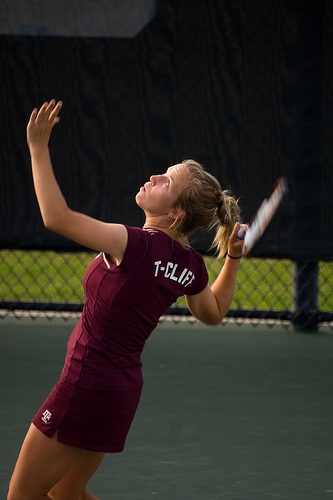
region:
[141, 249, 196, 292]
White letters on shirt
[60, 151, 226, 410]
Women wearing a red shirt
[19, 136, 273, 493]
The women is playing tennis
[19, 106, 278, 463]
The women is holding a tennis racket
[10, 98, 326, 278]
The tarp on the fence is black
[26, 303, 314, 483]
The court is green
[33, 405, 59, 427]
White logo on shorts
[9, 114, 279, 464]
The women is swinging the tennis racket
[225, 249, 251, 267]
The bracelet is black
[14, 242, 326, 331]
The chain link fence is black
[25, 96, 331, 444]
the player is looking up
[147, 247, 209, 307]
the text says T-Cliff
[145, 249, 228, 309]
the text is white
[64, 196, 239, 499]
the uniform is maroon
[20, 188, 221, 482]
the player is wearing a uniform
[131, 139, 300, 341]
the player is holding a racket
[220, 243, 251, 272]
the player is wearing a bracelet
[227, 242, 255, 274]
the bracelet is black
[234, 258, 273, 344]
grass outside the fence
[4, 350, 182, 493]
the skirt is maroon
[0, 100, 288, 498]
a female tennis player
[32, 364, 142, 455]
a dark red skirt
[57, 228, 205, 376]
a dark red sleeveless jersey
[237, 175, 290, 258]
a blurred tennis racket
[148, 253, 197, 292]
printed name T-CLIFF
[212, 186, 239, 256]
a woman's pony tail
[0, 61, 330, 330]
a black chain link fence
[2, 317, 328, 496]
a dark green tennis court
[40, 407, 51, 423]
a white corporate logo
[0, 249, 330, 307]
a light green patch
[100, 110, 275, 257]
woman is looking upwards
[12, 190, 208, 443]
woman's dress is burgundy colored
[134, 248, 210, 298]
white letters on woman's shirt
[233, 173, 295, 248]
woman holding a racket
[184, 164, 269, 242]
woman's hair in a bun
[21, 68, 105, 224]
woman's hand in the air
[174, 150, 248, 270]
woman's hair is blonde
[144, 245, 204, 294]
letters on shirt spell t-cliff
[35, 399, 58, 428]
white letters on side of dress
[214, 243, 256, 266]
woman wearing black rubber band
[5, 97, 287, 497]
a woman playing tennis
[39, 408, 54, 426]
a white logo on woman's skirt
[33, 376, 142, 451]
woman wearing a red skirt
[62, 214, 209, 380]
woman wearing a red shirt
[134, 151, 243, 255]
blonde woman with a pony tail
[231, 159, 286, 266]
a woman holding a tennis racket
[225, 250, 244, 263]
woman wearing a black bracelet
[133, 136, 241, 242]
a woman looking upward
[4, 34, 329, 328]
black tarp on a metal fence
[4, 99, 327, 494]
a tennis player on a tennis court